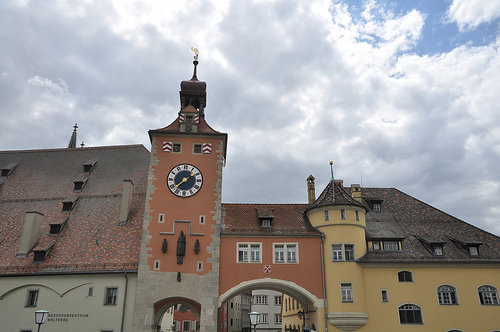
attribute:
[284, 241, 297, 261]
window — on a building